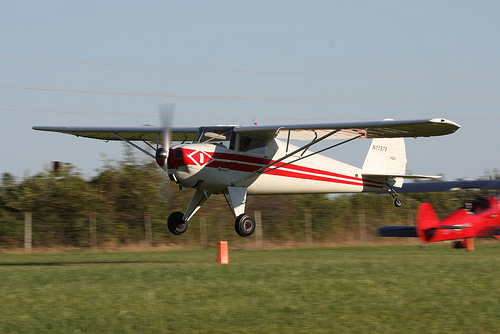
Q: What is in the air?
A: The plane.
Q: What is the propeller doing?
A: Turning?.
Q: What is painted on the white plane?
A: Red stripes.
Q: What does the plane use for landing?
A: Tires.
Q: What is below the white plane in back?
A: A wheel.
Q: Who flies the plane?
A: The pilot?.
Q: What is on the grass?
A: Plane.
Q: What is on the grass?
A: Plane.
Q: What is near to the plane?
A: Fencec.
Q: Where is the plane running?
A: Air.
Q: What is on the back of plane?
A: Wings.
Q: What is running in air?
A: Plane.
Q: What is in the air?
A: Plane.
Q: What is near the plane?
A: Fence.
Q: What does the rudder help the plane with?
A: Steering.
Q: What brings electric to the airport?
A: Power lines.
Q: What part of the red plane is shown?
A: The tail.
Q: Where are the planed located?
A: At the airport.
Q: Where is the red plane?
A: Ground.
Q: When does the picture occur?
A: Daytime.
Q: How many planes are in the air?
A: One.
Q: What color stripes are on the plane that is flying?
A: Red.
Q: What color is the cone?
A: Orange.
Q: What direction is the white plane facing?
A: Left.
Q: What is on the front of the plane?
A: Propeller.